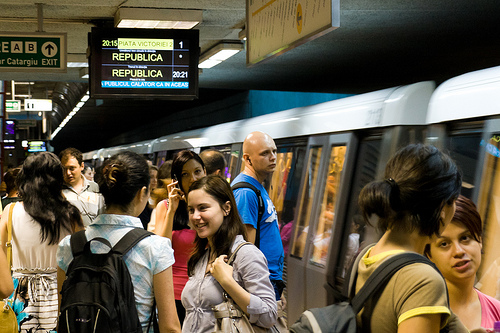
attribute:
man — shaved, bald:
[215, 133, 292, 291]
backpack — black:
[53, 228, 139, 325]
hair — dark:
[88, 138, 170, 226]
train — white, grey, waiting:
[72, 65, 500, 332]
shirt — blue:
[228, 164, 302, 284]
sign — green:
[1, 26, 68, 66]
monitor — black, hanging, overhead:
[89, 26, 193, 95]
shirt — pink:
[160, 189, 195, 303]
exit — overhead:
[37, 39, 61, 73]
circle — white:
[42, 36, 59, 55]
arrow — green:
[46, 44, 54, 53]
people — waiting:
[4, 141, 477, 321]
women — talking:
[345, 154, 498, 328]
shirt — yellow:
[345, 239, 441, 333]